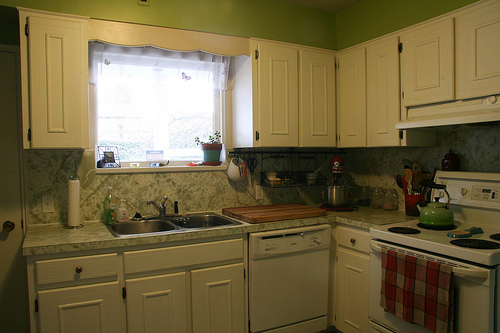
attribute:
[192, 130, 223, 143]
flowers — green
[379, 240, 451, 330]
towel — white, red, checkered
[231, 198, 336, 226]
board — wooden cutting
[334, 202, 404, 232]
top — counter 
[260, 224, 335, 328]
dishwasher — white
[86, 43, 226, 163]
window — square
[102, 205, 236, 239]
sink — silver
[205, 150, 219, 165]
paint — blue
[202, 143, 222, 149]
paint — burgandy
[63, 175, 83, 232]
roll — tall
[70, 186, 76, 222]
towel — paper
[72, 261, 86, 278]
knob — gold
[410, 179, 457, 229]
kettle — green, tea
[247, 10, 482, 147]
cabinets — white, wooden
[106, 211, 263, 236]
sink — silver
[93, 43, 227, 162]
curtain — sheer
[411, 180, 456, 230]
pot — tea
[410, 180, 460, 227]
teapot — green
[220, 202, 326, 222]
cutting board — wood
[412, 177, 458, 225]
kettle — green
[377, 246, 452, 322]
mat — checked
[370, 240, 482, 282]
handle — stove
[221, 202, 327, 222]
board — brown, wooden, cutting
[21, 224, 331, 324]
cabinets — cream, colored, kitchen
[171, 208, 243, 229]
sink — kitchen, stainless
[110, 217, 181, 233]
sink — kitchen, stainless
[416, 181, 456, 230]
tea kettle — green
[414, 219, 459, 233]
burner — rear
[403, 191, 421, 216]
utensil holder — red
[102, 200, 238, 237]
sink — double, silver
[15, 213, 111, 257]
kitchen counter — white, green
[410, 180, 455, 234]
kettle — green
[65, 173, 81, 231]
holder — metal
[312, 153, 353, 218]
mixer — red, metal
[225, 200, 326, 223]
cutting board — wooden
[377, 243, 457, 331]
towel — red, white, checkered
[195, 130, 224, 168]
plant — potted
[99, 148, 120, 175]
picture — framed